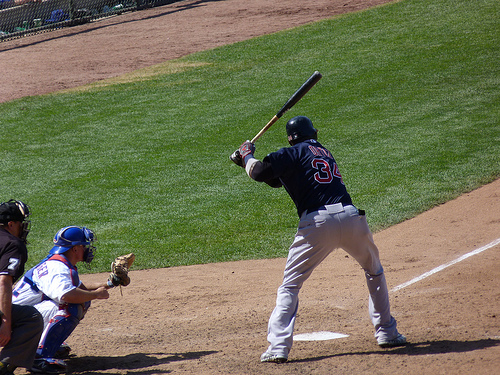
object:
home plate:
[280, 331, 355, 343]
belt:
[297, 200, 355, 217]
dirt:
[468, 285, 494, 298]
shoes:
[374, 329, 407, 347]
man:
[11, 226, 127, 367]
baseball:
[3, 3, 496, 371]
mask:
[81, 225, 97, 262]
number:
[331, 162, 346, 184]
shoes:
[257, 344, 291, 364]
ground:
[0, 45, 228, 183]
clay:
[459, 291, 483, 333]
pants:
[264, 203, 395, 355]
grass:
[0, 2, 498, 275]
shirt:
[4, 255, 81, 314]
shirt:
[0, 224, 30, 286]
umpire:
[0, 199, 43, 374]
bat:
[231, 69, 322, 162]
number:
[310, 159, 334, 186]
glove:
[111, 254, 134, 287]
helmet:
[283, 117, 318, 145]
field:
[6, 0, 498, 373]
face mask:
[17, 208, 32, 238]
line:
[384, 239, 499, 294]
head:
[284, 113, 320, 148]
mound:
[5, 254, 485, 367]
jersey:
[260, 136, 353, 218]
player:
[228, 116, 406, 364]